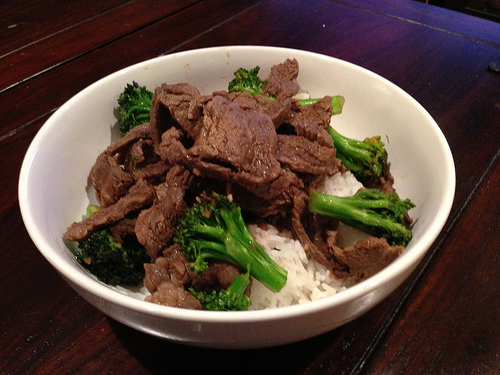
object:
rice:
[246, 223, 349, 312]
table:
[0, 2, 497, 371]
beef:
[89, 152, 136, 207]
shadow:
[126, 343, 327, 373]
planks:
[3, 6, 496, 374]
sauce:
[181, 54, 261, 81]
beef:
[63, 178, 154, 242]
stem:
[229, 235, 288, 293]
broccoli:
[118, 81, 154, 138]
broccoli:
[227, 66, 345, 116]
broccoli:
[325, 125, 389, 188]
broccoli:
[307, 188, 416, 246]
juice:
[185, 48, 232, 82]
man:
[191, 87, 283, 179]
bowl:
[16, 45, 457, 350]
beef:
[291, 190, 405, 284]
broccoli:
[174, 191, 287, 294]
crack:
[348, 156, 496, 375]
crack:
[2, 2, 51, 30]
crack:
[0, 285, 91, 366]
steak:
[65, 57, 412, 308]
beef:
[134, 164, 196, 262]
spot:
[323, 20, 326, 30]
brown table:
[1, 1, 497, 373]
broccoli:
[74, 203, 152, 287]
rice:
[321, 168, 361, 198]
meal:
[288, 258, 322, 301]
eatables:
[61, 57, 413, 310]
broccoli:
[184, 264, 253, 312]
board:
[385, 303, 497, 360]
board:
[43, 71, 71, 101]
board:
[78, 18, 116, 51]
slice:
[185, 95, 282, 182]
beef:
[183, 92, 305, 210]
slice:
[171, 103, 249, 223]